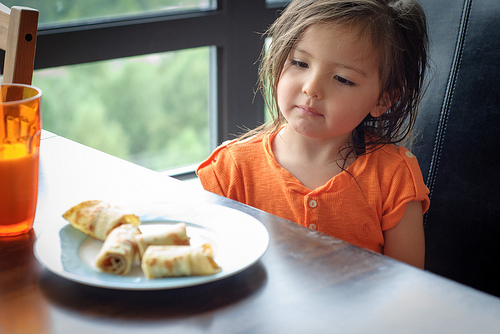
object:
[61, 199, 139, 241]
eggroll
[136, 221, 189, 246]
eggroll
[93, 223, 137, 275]
eggroll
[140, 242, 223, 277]
eggroll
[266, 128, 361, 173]
neck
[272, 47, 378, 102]
looking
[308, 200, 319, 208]
button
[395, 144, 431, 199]
strap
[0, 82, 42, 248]
cup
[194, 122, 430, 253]
shirt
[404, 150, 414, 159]
button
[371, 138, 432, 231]
shirt sleeves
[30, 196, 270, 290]
plate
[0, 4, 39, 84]
chair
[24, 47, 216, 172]
tree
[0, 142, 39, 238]
drink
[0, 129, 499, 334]
table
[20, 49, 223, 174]
landscape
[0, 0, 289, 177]
wall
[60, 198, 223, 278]
food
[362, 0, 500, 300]
booth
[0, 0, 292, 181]
window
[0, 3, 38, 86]
back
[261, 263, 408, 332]
light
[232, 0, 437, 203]
hair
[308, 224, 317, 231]
button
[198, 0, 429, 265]
girl